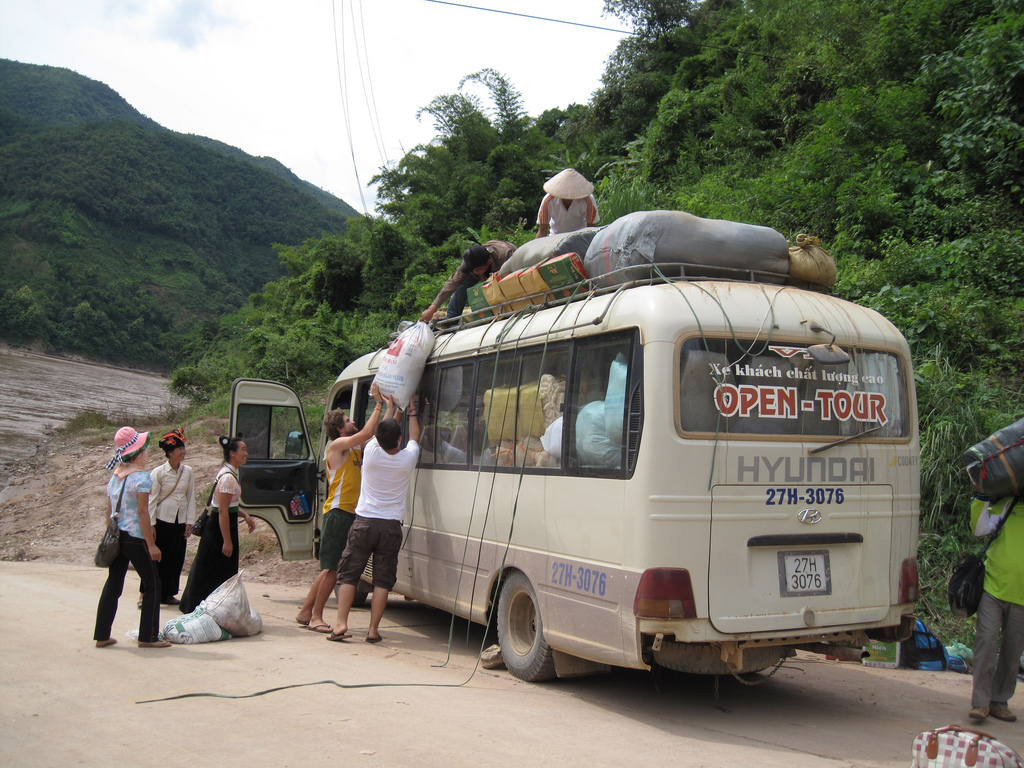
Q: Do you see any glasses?
A: No, there are no glasses.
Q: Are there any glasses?
A: No, there are no glasses.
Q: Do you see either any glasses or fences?
A: No, there are no glasses or fences.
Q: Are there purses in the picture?
A: Yes, there is a purse.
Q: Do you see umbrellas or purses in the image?
A: Yes, there is a purse.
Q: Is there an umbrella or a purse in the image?
A: Yes, there is a purse.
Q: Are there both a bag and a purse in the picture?
A: Yes, there are both a purse and a bag.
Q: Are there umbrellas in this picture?
A: No, there are no umbrellas.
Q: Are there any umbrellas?
A: No, there are no umbrellas.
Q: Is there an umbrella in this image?
A: No, there are no umbrellas.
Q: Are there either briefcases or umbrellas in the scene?
A: No, there are no umbrellas or briefcases.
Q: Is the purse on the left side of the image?
A: Yes, the purse is on the left of the image.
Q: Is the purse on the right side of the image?
A: No, the purse is on the left of the image.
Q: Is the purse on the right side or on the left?
A: The purse is on the left of the image.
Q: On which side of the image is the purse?
A: The purse is on the left of the image.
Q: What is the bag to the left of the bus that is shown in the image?
A: The bag is a purse.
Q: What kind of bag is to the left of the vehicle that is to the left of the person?
A: The bag is a purse.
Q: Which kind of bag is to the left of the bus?
A: The bag is a purse.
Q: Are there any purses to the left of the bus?
A: Yes, there is a purse to the left of the bus.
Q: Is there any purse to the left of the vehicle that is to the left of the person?
A: Yes, there is a purse to the left of the bus.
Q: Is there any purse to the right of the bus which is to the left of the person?
A: No, the purse is to the left of the bus.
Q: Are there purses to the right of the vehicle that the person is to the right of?
A: No, the purse is to the left of the bus.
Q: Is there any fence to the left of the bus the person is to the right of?
A: No, there is a purse to the left of the bus.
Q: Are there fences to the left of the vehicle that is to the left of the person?
A: No, there is a purse to the left of the bus.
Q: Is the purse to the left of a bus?
A: Yes, the purse is to the left of a bus.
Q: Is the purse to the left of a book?
A: No, the purse is to the left of a bus.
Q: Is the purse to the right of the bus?
A: No, the purse is to the left of the bus.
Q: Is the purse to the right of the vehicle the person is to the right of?
A: No, the purse is to the left of the bus.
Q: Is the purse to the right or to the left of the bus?
A: The purse is to the left of the bus.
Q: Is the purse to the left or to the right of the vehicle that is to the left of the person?
A: The purse is to the left of the bus.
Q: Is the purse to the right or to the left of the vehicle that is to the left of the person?
A: The purse is to the left of the bus.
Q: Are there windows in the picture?
A: Yes, there is a window.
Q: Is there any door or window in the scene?
A: Yes, there is a window.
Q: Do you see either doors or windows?
A: Yes, there is a window.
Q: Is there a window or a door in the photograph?
A: Yes, there is a window.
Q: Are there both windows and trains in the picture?
A: No, there is a window but no trains.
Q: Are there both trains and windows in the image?
A: No, there is a window but no trains.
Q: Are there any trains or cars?
A: No, there are no cars or trains.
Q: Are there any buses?
A: Yes, there is a bus.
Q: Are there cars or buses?
A: Yes, there is a bus.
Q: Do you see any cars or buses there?
A: Yes, there is a bus.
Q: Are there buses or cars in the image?
A: Yes, there is a bus.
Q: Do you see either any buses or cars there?
A: Yes, there is a bus.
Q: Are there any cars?
A: No, there are no cars.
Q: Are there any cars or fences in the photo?
A: No, there are no cars or fences.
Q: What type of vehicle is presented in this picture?
A: The vehicle is a bus.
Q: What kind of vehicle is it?
A: The vehicle is a bus.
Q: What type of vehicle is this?
A: That is a bus.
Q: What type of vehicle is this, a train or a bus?
A: That is a bus.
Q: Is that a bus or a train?
A: That is a bus.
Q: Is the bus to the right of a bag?
A: Yes, the bus is to the right of a bag.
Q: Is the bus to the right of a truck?
A: No, the bus is to the right of a bag.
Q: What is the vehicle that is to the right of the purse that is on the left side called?
A: The vehicle is a bus.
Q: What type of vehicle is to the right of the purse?
A: The vehicle is a bus.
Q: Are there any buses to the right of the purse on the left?
A: Yes, there is a bus to the right of the purse.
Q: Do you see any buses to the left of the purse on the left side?
A: No, the bus is to the right of the purse.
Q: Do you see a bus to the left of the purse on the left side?
A: No, the bus is to the right of the purse.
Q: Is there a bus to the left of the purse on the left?
A: No, the bus is to the right of the purse.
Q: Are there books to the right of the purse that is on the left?
A: No, there is a bus to the right of the purse.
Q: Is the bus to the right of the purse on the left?
A: Yes, the bus is to the right of the purse.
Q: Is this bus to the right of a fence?
A: No, the bus is to the right of the purse.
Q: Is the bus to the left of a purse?
A: No, the bus is to the right of a purse.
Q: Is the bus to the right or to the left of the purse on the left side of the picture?
A: The bus is to the right of the purse.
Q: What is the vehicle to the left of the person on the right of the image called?
A: The vehicle is a bus.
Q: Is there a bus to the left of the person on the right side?
A: Yes, there is a bus to the left of the person.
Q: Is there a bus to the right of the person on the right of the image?
A: No, the bus is to the left of the person.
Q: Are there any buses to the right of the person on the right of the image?
A: No, the bus is to the left of the person.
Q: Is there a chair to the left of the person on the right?
A: No, there is a bus to the left of the person.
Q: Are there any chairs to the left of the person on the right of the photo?
A: No, there is a bus to the left of the person.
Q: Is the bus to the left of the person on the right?
A: Yes, the bus is to the left of the person.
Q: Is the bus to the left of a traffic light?
A: No, the bus is to the left of the person.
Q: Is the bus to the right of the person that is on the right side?
A: No, the bus is to the left of the person.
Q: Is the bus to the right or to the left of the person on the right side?
A: The bus is to the left of the person.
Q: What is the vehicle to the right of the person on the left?
A: The vehicle is a bus.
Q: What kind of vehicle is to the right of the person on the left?
A: The vehicle is a bus.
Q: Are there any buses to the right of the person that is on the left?
A: Yes, there is a bus to the right of the person.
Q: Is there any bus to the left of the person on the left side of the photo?
A: No, the bus is to the right of the person.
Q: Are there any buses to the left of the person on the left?
A: No, the bus is to the right of the person.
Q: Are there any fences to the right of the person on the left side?
A: No, there is a bus to the right of the person.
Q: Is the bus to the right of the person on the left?
A: Yes, the bus is to the right of the person.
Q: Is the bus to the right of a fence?
A: No, the bus is to the right of the person.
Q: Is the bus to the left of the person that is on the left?
A: No, the bus is to the right of the person.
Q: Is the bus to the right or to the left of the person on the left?
A: The bus is to the right of the person.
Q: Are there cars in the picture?
A: No, there are no cars.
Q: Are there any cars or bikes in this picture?
A: No, there are no cars or bikes.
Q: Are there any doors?
A: Yes, there is a door.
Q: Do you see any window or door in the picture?
A: Yes, there is a door.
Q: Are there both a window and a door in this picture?
A: Yes, there are both a door and a window.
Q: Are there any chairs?
A: No, there are no chairs.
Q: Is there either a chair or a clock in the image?
A: No, there are no chairs or clocks.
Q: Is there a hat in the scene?
A: Yes, there is a hat.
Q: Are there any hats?
A: Yes, there is a hat.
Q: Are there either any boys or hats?
A: Yes, there is a hat.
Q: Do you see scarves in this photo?
A: No, there are no scarves.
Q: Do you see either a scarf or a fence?
A: No, there are no scarves or fences.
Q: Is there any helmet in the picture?
A: No, there are no helmets.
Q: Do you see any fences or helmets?
A: No, there are no helmets or fences.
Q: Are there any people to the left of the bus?
A: Yes, there is a person to the left of the bus.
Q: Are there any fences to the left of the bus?
A: No, there is a person to the left of the bus.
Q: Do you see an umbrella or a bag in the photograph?
A: Yes, there is a bag.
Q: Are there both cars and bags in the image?
A: No, there is a bag but no cars.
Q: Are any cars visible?
A: No, there are no cars.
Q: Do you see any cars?
A: No, there are no cars.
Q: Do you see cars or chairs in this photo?
A: No, there are no cars or chairs.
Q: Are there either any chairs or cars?
A: No, there are no cars or chairs.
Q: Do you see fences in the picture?
A: No, there are no fences.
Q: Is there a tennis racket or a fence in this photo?
A: No, there are no fences or rackets.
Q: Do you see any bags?
A: Yes, there is a bag.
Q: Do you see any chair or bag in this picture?
A: Yes, there is a bag.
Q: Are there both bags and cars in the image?
A: No, there is a bag but no cars.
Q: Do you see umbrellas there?
A: No, there are no umbrellas.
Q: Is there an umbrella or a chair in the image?
A: No, there are no umbrellas or chairs.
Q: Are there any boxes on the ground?
A: No, there is a bag on the ground.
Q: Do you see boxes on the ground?
A: No, there is a bag on the ground.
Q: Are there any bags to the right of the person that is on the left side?
A: Yes, there is a bag to the right of the person.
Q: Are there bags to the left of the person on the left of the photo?
A: No, the bag is to the right of the person.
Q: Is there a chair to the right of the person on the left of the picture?
A: No, there is a bag to the right of the person.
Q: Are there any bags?
A: Yes, there is a bag.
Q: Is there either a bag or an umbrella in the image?
A: Yes, there is a bag.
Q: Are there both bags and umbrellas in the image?
A: No, there is a bag but no umbrellas.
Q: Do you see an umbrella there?
A: No, there are no umbrellas.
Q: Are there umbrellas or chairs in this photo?
A: No, there are no umbrellas or chairs.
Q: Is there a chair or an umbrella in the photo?
A: No, there are no umbrellas or chairs.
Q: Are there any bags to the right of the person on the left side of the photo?
A: Yes, there is a bag to the right of the person.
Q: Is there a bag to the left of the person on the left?
A: No, the bag is to the right of the person.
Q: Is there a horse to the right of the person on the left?
A: No, there is a bag to the right of the person.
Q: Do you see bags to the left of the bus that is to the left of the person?
A: Yes, there is a bag to the left of the bus.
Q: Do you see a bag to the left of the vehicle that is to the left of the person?
A: Yes, there is a bag to the left of the bus.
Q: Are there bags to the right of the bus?
A: No, the bag is to the left of the bus.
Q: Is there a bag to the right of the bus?
A: No, the bag is to the left of the bus.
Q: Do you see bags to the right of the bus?
A: No, the bag is to the left of the bus.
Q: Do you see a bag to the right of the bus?
A: No, the bag is to the left of the bus.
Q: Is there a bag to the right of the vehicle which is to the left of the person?
A: No, the bag is to the left of the bus.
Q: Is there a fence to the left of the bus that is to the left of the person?
A: No, there is a bag to the left of the bus.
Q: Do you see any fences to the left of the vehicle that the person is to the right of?
A: No, there is a bag to the left of the bus.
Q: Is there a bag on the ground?
A: Yes, there is a bag on the ground.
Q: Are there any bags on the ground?
A: Yes, there is a bag on the ground.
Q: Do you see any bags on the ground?
A: Yes, there is a bag on the ground.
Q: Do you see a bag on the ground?
A: Yes, there is a bag on the ground.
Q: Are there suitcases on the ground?
A: No, there is a bag on the ground.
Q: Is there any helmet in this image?
A: No, there are no helmets.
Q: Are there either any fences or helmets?
A: No, there are no helmets or fences.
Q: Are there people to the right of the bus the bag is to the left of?
A: Yes, there is a person to the right of the bus.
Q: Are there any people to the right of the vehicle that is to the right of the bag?
A: Yes, there is a person to the right of the bus.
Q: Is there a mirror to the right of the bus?
A: No, there is a person to the right of the bus.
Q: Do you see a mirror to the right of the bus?
A: No, there is a person to the right of the bus.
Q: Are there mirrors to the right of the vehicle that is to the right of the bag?
A: No, there is a person to the right of the bus.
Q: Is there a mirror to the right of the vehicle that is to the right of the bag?
A: No, there is a person to the right of the bus.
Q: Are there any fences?
A: No, there are no fences.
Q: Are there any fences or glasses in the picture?
A: No, there are no fences or glasses.